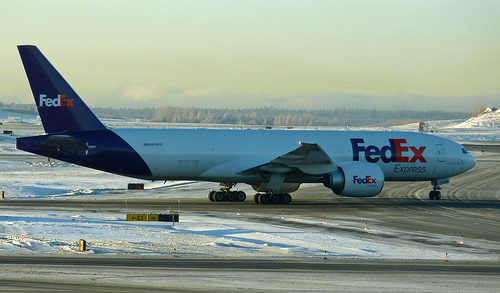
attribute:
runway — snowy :
[0, 149, 497, 289]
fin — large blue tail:
[4, 34, 83, 138]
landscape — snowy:
[1, 100, 496, 291]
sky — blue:
[0, 1, 498, 111]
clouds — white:
[109, 87, 475, 109]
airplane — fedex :
[10, 40, 480, 210]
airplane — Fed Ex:
[47, 40, 474, 225]